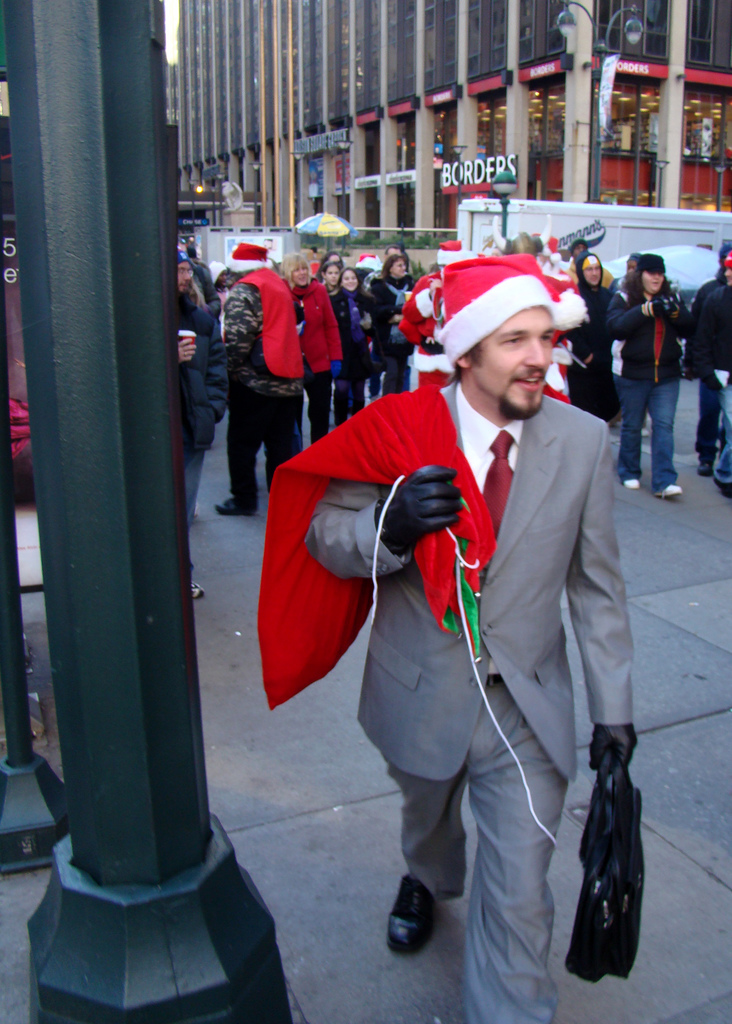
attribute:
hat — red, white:
[435, 244, 556, 367]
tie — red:
[477, 429, 516, 583]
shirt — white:
[451, 377, 552, 546]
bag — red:
[257, 375, 499, 725]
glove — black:
[373, 456, 467, 553]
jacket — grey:
[309, 380, 641, 795]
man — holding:
[258, 244, 644, 1017]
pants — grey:
[389, 672, 575, 1020]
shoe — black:
[382, 873, 442, 959]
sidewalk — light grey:
[11, 320, 725, 1011]